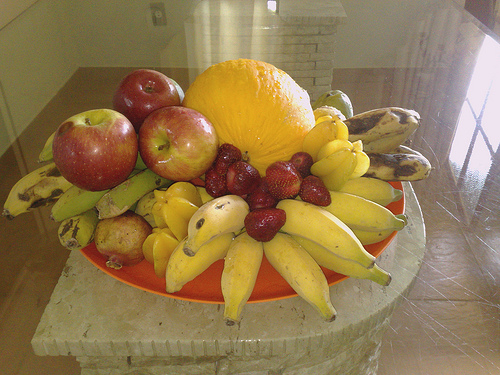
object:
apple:
[51, 108, 138, 192]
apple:
[113, 69, 180, 134]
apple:
[138, 105, 219, 182]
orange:
[183, 59, 316, 179]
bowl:
[77, 181, 403, 306]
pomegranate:
[94, 209, 152, 269]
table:
[30, 294, 158, 342]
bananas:
[48, 185, 109, 224]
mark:
[344, 110, 388, 134]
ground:
[425, 259, 499, 375]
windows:
[447, 34, 499, 229]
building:
[0, 0, 500, 375]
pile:
[77, 99, 371, 268]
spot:
[155, 178, 162, 186]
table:
[30, 180, 426, 375]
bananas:
[57, 207, 98, 251]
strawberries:
[211, 137, 241, 173]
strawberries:
[227, 161, 261, 195]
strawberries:
[247, 176, 280, 210]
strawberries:
[299, 175, 332, 207]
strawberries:
[205, 163, 232, 198]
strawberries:
[290, 151, 314, 178]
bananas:
[340, 177, 403, 207]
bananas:
[351, 214, 408, 245]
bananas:
[274, 199, 377, 269]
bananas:
[292, 236, 392, 287]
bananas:
[127, 150, 148, 178]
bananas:
[164, 232, 235, 294]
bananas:
[220, 228, 263, 325]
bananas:
[94, 167, 172, 219]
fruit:
[0, 59, 435, 327]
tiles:
[419, 268, 500, 375]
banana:
[181, 194, 251, 257]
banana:
[1, 162, 74, 220]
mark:
[59, 219, 80, 240]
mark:
[215, 204, 225, 210]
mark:
[46, 166, 63, 179]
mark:
[27, 198, 46, 210]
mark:
[52, 188, 65, 196]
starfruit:
[152, 181, 200, 242]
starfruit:
[141, 227, 179, 276]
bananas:
[262, 232, 337, 322]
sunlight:
[482, 47, 499, 134]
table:
[77, 318, 342, 363]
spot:
[58, 121, 74, 135]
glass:
[446, 33, 499, 230]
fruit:
[33, 62, 405, 293]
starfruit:
[310, 139, 371, 190]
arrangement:
[0, 60, 437, 326]